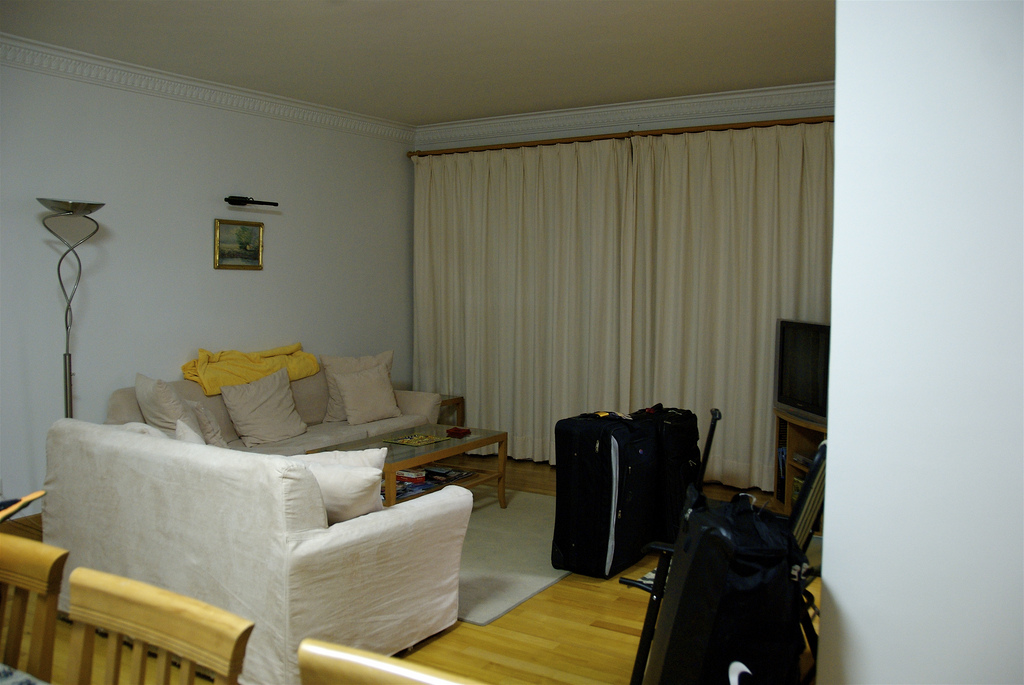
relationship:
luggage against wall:
[631, 493, 816, 681] [818, 2, 1019, 682]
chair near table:
[47, 564, 257, 682] [7, 647, 34, 680]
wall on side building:
[818, 2, 1019, 682] [0, 0, 1024, 684]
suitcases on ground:
[629, 438, 842, 682] [0, 441, 836, 680]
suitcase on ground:
[622, 403, 707, 548] [0, 441, 836, 680]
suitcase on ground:
[553, 411, 650, 581] [0, 441, 836, 680]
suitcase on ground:
[619, 396, 724, 567] [0, 441, 836, 680]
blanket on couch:
[177, 340, 323, 402] [109, 353, 442, 462]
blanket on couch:
[183, 342, 322, 396] [103, 352, 440, 474]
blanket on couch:
[183, 342, 322, 396] [109, 353, 442, 462]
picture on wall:
[214, 219, 264, 270] [3, 34, 415, 513]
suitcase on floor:
[553, 411, 650, 581] [394, 453, 818, 682]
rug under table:
[441, 489, 577, 623] [332, 419, 503, 518]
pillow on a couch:
[331, 360, 405, 425] [104, 360, 440, 458]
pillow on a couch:
[223, 374, 306, 441] [103, 352, 440, 474]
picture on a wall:
[212, 216, 264, 273] [3, 34, 415, 513]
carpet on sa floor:
[451, 493, 569, 623] [394, 453, 818, 682]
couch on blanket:
[109, 353, 442, 462] [182, 338, 319, 390]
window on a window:
[411, 120, 834, 493] [400, 117, 822, 493]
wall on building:
[3, 34, 415, 513] [0, 0, 1024, 684]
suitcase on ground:
[544, 402, 649, 581] [0, 441, 836, 680]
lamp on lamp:
[36, 197, 104, 421] [36, 197, 104, 421]